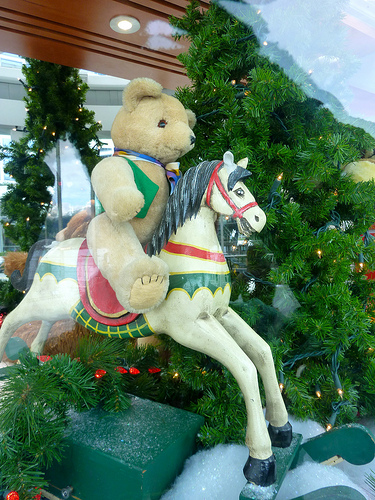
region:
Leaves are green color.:
[244, 126, 320, 198]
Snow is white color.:
[189, 453, 224, 498]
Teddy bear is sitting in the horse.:
[68, 113, 224, 291]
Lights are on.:
[4, 70, 317, 344]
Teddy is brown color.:
[90, 114, 197, 263]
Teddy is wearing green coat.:
[100, 139, 176, 233]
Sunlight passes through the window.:
[0, 82, 164, 226]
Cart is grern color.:
[242, 423, 373, 497]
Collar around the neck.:
[103, 131, 180, 182]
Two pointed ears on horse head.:
[216, 148, 259, 173]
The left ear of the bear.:
[119, 73, 159, 110]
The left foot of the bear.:
[124, 248, 172, 308]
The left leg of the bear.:
[95, 212, 145, 270]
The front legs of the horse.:
[202, 317, 295, 486]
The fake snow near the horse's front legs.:
[197, 420, 299, 498]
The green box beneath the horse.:
[40, 376, 195, 495]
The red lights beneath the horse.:
[86, 362, 166, 382]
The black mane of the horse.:
[163, 152, 218, 235]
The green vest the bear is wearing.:
[115, 156, 160, 221]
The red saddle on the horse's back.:
[78, 240, 138, 326]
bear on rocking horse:
[0, 76, 292, 487]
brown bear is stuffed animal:
[84, 76, 198, 312]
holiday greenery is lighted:
[0, 0, 373, 498]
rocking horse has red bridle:
[204, 161, 256, 219]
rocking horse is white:
[1, 151, 292, 486]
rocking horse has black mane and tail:
[10, 159, 251, 293]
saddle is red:
[75, 237, 139, 325]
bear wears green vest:
[98, 154, 156, 219]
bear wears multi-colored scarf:
[113, 147, 182, 194]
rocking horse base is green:
[43, 381, 373, 499]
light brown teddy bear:
[97, 80, 197, 307]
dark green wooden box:
[32, 395, 228, 493]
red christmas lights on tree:
[82, 360, 175, 388]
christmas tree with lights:
[232, 82, 368, 345]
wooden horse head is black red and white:
[184, 152, 267, 279]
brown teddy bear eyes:
[149, 117, 173, 137]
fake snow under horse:
[193, 453, 234, 494]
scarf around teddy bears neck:
[109, 143, 189, 186]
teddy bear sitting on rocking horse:
[18, 153, 283, 473]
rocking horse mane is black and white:
[166, 159, 216, 238]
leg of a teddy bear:
[87, 209, 169, 314]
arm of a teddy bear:
[90, 152, 146, 225]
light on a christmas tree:
[266, 171, 286, 196]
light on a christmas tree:
[33, 353, 55, 364]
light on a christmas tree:
[92, 367, 109, 380]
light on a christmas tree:
[111, 363, 128, 374]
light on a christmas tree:
[126, 363, 141, 376]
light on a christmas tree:
[146, 364, 164, 374]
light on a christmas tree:
[275, 366, 288, 393]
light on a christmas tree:
[313, 378, 322, 401]